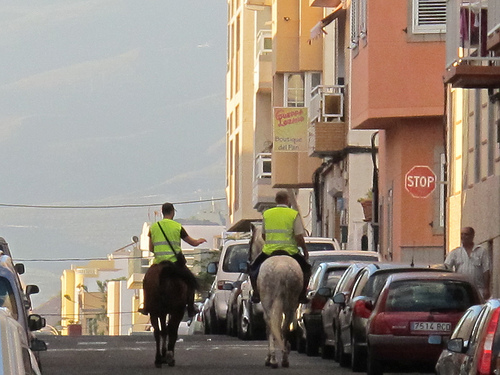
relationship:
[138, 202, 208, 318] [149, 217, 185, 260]
man wearing bright vest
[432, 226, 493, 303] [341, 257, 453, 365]
man standing car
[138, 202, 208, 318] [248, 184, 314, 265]
man looking horse rider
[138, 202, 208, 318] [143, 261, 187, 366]
man riding horse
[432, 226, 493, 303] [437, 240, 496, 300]
man wearing shirt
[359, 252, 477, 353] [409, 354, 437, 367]
car parked curb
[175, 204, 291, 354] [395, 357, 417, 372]
van parked curb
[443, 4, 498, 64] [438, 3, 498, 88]
railing on patio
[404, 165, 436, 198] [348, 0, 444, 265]
sign on building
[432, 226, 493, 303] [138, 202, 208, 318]
man watch man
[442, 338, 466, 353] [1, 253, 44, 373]
mirror on side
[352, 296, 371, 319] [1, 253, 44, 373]
mirror on side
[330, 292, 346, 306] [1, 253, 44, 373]
mirror on side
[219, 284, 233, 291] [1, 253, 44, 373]
mirror on side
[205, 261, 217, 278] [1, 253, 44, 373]
mirror on side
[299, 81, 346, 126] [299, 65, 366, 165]
balacony on second floor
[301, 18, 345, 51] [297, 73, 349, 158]
awning on balcony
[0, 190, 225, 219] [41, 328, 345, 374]
line over road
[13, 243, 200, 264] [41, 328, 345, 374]
line over road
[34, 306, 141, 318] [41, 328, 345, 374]
line over road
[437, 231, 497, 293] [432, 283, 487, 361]
man walks on sidewalk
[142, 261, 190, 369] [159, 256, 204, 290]
black horse has tail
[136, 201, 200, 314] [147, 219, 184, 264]
man wears vest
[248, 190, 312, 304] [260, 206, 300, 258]
horse rider wears vest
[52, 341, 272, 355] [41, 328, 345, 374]
white lines on road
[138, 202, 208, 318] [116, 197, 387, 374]
man riding horses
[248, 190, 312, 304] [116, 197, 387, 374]
horse rider riding horses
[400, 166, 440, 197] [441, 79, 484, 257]
sign attached to building